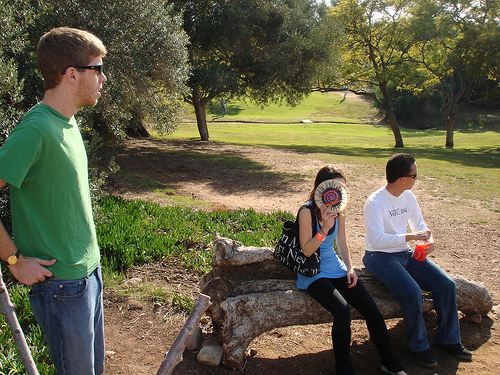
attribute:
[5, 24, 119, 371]
man — standing, here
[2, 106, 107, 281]
shirt — green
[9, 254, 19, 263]
face — gold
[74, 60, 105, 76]
sunglasses — black, dark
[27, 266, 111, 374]
jeans — blue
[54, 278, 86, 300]
rivets — metal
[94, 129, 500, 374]
path — gravel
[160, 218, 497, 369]
log — large, tree's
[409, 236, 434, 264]
bottle — plastic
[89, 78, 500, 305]
grass — green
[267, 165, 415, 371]
person — sitting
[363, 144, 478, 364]
person — sitting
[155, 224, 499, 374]
stump — tree's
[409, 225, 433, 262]
gatorade — here, red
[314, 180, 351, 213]
frisbee — white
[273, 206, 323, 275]
purse — black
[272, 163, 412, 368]
woman — here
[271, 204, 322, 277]
bag — black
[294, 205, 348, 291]
shirt — blue, woman's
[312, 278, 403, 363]
pants — black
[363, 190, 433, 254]
shirt — white, man's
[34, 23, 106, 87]
hair — short, man's, brown, neat, tidy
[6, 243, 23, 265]
band — dark